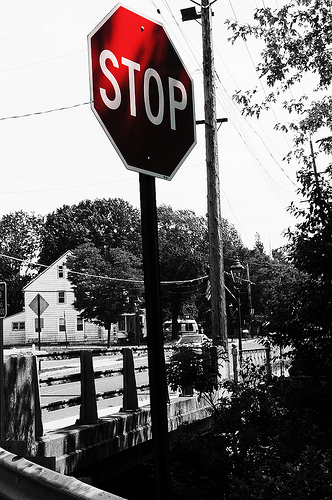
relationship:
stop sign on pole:
[86, 1, 197, 180] [138, 170, 172, 498]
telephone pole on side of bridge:
[189, 0, 228, 351] [2, 343, 295, 472]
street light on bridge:
[229, 254, 245, 376] [2, 343, 295, 472]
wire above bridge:
[1, 101, 92, 122] [2, 343, 295, 472]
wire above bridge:
[228, 0, 256, 67] [2, 343, 295, 472]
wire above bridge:
[260, 1, 265, 13] [2, 343, 295, 472]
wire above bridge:
[0, 253, 208, 284] [2, 343, 295, 472]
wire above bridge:
[223, 269, 258, 285] [2, 343, 295, 472]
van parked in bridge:
[162, 319, 199, 340] [2, 343, 295, 472]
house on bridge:
[21, 249, 137, 346] [2, 343, 295, 472]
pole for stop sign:
[138, 170, 172, 498] [86, 1, 197, 180]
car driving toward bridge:
[173, 333, 213, 355] [2, 343, 231, 473]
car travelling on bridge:
[173, 333, 213, 355] [2, 343, 295, 472]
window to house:
[58, 290, 66, 304] [21, 249, 137, 346]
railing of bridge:
[36, 345, 178, 362] [2, 343, 231, 473]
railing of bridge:
[39, 364, 149, 387] [2, 343, 231, 473]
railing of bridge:
[40, 382, 150, 412] [2, 343, 231, 473]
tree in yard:
[64, 243, 146, 348] [2, 344, 147, 353]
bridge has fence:
[2, 343, 231, 473] [5, 344, 232, 439]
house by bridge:
[21, 249, 137, 346] [2, 343, 295, 472]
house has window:
[21, 249, 137, 346] [58, 290, 66, 304]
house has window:
[21, 249, 137, 346] [57, 264, 65, 278]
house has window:
[21, 249, 137, 346] [76, 319, 84, 332]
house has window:
[21, 249, 137, 346] [58, 317, 68, 335]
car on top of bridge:
[173, 333, 213, 355] [2, 343, 231, 473]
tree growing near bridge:
[64, 243, 146, 348] [2, 343, 295, 472]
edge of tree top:
[68, 244, 139, 258] [65, 242, 147, 329]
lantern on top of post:
[229, 256, 245, 286] [236, 284, 244, 374]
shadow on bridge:
[5, 349, 217, 459] [2, 343, 231, 473]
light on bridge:
[5, 347, 233, 454] [2, 343, 231, 473]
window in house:
[76, 319, 84, 332] [21, 249, 137, 346]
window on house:
[58, 317, 68, 335] [21, 249, 137, 346]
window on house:
[58, 290, 66, 304] [21, 249, 137, 346]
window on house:
[57, 264, 65, 278] [21, 249, 137, 346]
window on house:
[76, 319, 84, 332] [21, 249, 137, 346]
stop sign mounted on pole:
[86, 1, 197, 180] [138, 170, 172, 498]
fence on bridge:
[5, 344, 232, 439] [2, 343, 231, 473]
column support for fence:
[2, 353, 44, 440] [5, 344, 232, 439]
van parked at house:
[162, 319, 199, 340] [21, 249, 137, 346]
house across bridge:
[21, 249, 137, 346] [2, 343, 295, 472]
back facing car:
[29, 295, 50, 316] [173, 333, 213, 355]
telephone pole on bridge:
[189, 0, 228, 351] [2, 343, 295, 472]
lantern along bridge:
[229, 256, 245, 286] [2, 343, 295, 472]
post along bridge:
[236, 284, 244, 374] [2, 343, 295, 472]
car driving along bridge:
[173, 333, 213, 355] [2, 343, 231, 473]